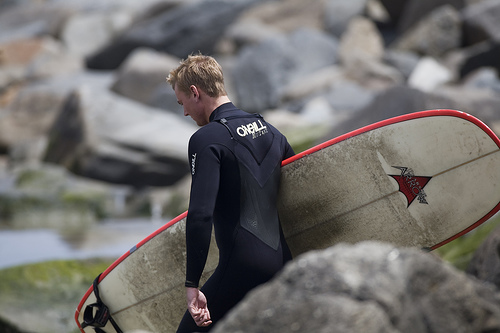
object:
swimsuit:
[175, 102, 296, 332]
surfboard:
[75, 108, 497, 332]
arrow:
[392, 173, 431, 207]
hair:
[166, 53, 223, 95]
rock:
[43, 87, 199, 185]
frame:
[74, 108, 498, 333]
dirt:
[123, 129, 442, 331]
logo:
[388, 164, 430, 211]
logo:
[236, 118, 268, 140]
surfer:
[166, 53, 294, 333]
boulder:
[208, 241, 500, 333]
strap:
[83, 273, 121, 332]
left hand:
[187, 289, 211, 324]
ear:
[188, 84, 201, 103]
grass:
[0, 213, 499, 285]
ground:
[0, 160, 499, 333]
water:
[0, 219, 172, 270]